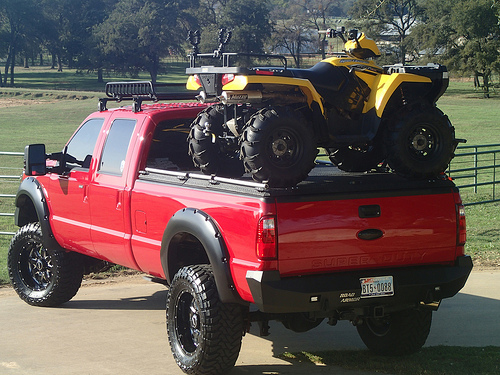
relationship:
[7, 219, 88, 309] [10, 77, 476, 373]
wheel on truck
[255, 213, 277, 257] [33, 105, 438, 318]
light on truck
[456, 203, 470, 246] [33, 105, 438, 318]
light on truck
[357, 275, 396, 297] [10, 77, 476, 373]
plate on truck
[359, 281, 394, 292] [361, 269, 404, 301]
black writing on license plate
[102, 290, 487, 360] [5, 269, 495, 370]
shadows on ground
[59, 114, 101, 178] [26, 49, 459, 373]
windows are on truck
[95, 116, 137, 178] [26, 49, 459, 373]
window are on truck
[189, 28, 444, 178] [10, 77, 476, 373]
vehicle on truck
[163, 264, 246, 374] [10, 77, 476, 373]
wheel on truck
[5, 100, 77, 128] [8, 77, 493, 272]
grass on ground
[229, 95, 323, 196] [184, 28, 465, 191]
tire on vehicle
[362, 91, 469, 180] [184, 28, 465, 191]
tire on vehicle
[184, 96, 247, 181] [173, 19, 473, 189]
tire on vehicle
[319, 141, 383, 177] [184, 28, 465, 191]
tire on vehicle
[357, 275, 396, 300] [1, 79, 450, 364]
plate on truck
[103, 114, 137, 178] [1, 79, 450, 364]
window on truck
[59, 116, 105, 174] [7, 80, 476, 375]
windows on truck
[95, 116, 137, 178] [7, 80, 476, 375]
window on truck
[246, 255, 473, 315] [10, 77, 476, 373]
bumper on back of truck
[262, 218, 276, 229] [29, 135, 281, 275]
light on back of truck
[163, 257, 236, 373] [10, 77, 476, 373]
wheel on back of truck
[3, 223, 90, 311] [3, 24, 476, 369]
wheel on front of truck